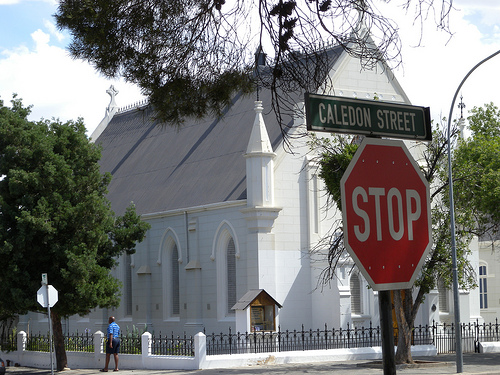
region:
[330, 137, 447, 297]
red and white octagonal stop sign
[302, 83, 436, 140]
green and white street sign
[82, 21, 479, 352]
tall white religious building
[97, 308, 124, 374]
man wearing a blue tee shirt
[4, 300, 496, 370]
black wrought iron fence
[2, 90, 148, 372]
big bushy ever green tree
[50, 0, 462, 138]
over hanging ever green tree branch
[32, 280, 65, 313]
back of a stop sing across the street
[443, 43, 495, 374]
grey metal street lamp pole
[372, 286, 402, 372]
black metal stop sign pole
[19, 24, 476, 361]
a church on a corner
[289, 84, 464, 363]
a stop sign on the street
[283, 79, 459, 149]
a street sign in a neighborhood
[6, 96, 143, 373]
a man by a tree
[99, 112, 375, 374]
a white church building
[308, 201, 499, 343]
the church building is white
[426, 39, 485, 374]
a lampole on the steet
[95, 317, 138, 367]
this man is wearing a blue shirt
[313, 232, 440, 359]
the entrance of the church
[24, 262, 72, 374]
the back side of a stop sign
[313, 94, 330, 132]
White letter on green sign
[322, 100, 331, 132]
White letter on green sign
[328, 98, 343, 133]
White letter on green sign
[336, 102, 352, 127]
White letter on green sign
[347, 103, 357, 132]
White letter on green sign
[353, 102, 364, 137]
White letter on green sign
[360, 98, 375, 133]
White letter on green sign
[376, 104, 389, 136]
White letter on green sign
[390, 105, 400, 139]
White letter on green sign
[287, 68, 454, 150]
Green and whie street sign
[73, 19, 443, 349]
this church is mostly white in color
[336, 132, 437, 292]
a stop sign stands in front of the church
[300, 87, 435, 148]
we are at Caledon Street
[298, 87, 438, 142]
this street sign is green and white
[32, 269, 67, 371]
a matching stop sign is located across the street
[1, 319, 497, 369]
a fence has been constructed around the church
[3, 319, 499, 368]
the fence around the church is wrought iron and block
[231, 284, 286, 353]
a small board lists information from the church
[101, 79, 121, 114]
a cross decorates the far end of the roof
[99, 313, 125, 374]
a pedestrian walks past the church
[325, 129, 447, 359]
Red and white traffic sign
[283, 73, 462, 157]
Green and white street sign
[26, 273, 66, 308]
Traffic sign on a pole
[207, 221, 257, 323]
Large window on a building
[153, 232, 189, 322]
Large window on a building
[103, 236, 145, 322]
Large window on a building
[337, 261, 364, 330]
Large window on a building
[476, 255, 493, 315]
Large window on a building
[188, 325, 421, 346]
Small black fence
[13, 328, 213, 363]
Lonmg black fence on grass